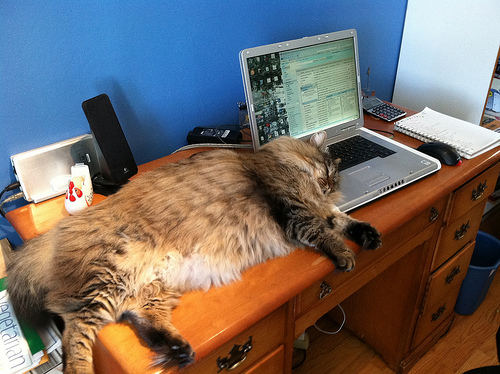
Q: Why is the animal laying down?
A: It's sleeping.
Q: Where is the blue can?
A: On the floor.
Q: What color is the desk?
A: Brown.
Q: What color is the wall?
A: Blue.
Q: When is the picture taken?
A: Day time.